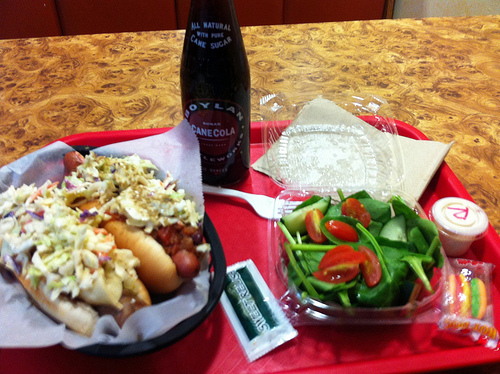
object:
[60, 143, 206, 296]
hotdog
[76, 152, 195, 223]
toppings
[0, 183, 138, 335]
hotdog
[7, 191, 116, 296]
toppings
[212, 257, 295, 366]
relish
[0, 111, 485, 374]
tray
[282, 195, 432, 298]
salad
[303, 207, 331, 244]
tomato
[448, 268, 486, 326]
candy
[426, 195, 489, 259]
container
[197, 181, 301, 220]
fork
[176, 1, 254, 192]
bottle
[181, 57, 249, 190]
soda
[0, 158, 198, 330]
food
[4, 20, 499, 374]
table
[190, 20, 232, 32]
text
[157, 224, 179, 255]
chili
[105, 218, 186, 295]
bun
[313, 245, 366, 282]
tomato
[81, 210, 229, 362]
basket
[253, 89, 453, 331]
container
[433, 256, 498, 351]
bag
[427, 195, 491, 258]
dressing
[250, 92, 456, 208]
napkin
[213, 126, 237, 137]
cola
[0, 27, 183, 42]
edge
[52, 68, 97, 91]
part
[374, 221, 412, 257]
vegetables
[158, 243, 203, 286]
portion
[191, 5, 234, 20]
part